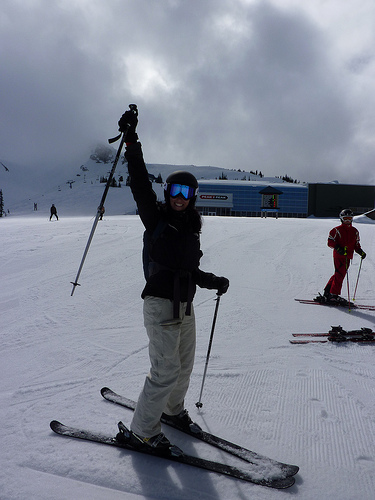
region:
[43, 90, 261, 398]
a woman holding up a ski pole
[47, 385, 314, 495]
a pair of snow skis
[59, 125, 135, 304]
a silver and black ski pole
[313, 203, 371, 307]
a red ski outfit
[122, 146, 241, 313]
a woman wearing a blue jacket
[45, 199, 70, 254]
a person skiing down the slope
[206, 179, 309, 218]
a blue and white building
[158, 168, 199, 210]
a woman wearing a ski helmet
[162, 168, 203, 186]
a black ski helmet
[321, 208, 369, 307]
a man holding two ski poles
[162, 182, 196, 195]
Blue goggles in the photo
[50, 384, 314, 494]
Ice skating gear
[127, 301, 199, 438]
Gray pants in the photo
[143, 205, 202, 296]
Black sweater in the photo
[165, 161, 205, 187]
Black helmet in the photo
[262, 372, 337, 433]
Ice covered surface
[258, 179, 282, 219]
A hut in the photo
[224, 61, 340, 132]
Clouds in the sky.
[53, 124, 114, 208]
Mountain in the background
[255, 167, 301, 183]
Trees in the photo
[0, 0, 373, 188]
the clouds in the sky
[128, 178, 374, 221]
the building in the back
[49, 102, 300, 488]
the woman getting ready to ski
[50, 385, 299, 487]
the skis under the woman's feet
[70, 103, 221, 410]
the ski poles in the woman's hands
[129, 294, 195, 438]
the light colored pants on the woman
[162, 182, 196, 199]
the protective eyewear on the woman's face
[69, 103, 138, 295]
the ski pole being held in the air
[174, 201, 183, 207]
the smile on the woman's face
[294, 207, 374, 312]
the person dressed in all red and ready to ski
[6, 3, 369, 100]
dark clouds in the sky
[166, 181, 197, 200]
blue goggles on the woman's eyes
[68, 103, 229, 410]
two ski poles in the woman's hands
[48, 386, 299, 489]
two black skis on the woman's feet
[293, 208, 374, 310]
a skier in red winter clothing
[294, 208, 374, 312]
a skier in red standing on the snow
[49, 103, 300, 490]
a female skier raising a ski pole in the right hand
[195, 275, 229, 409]
a ski pole in the woman's right hand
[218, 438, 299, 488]
snow on top of the skis in the front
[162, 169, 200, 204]
a black protective helmet on the woman's head